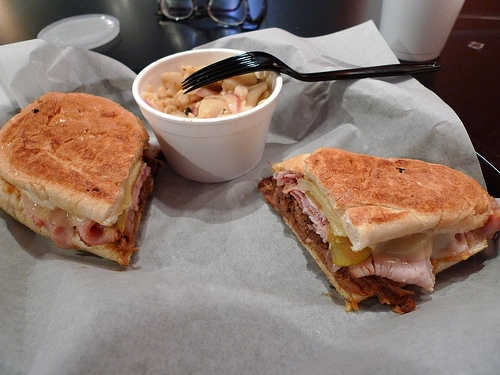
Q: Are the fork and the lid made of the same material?
A: Yes, both the fork and the lid are made of plastic.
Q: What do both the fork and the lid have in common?
A: The material, both the fork and the lid are plastic.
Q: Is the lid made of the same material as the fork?
A: Yes, both the lid and the fork are made of plastic.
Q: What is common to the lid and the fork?
A: The material, both the lid and the fork are plastic.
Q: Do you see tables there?
A: Yes, there is a table.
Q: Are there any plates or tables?
A: Yes, there is a table.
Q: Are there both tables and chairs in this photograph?
A: No, there is a table but no chairs.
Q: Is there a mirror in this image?
A: No, there are no mirrors.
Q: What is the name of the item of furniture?
A: The piece of furniture is a table.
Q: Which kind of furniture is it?
A: The piece of furniture is a table.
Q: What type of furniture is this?
A: That is a table.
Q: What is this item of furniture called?
A: That is a table.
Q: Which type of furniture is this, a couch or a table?
A: That is a table.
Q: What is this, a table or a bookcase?
A: This is a table.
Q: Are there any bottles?
A: No, there are no bottles.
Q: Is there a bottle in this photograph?
A: No, there are no bottles.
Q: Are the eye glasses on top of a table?
A: Yes, the eye glasses are on top of a table.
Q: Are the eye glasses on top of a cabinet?
A: No, the eye glasses are on top of a table.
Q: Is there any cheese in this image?
A: Yes, there is cheese.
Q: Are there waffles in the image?
A: No, there are no waffles.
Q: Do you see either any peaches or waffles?
A: No, there are no waffles or peaches.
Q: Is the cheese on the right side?
A: Yes, the cheese is on the right of the image.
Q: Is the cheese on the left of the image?
A: No, the cheese is on the right of the image.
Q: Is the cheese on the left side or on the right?
A: The cheese is on the right of the image.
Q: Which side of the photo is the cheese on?
A: The cheese is on the right of the image.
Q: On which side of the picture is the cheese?
A: The cheese is on the right of the image.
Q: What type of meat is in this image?
A: The meat is ham.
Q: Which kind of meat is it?
A: The meat is ham.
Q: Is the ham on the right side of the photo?
A: Yes, the ham is on the right of the image.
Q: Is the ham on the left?
A: No, the ham is on the right of the image.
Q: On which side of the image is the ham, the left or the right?
A: The ham is on the right of the image.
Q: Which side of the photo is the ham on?
A: The ham is on the right of the image.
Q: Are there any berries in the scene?
A: No, there are no berries.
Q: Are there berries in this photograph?
A: No, there are no berries.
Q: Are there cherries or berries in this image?
A: No, there are no berries or cherries.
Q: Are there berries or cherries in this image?
A: No, there are no berries or cherries.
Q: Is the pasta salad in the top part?
A: Yes, the pasta salad is in the top of the image.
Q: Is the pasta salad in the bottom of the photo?
A: No, the pasta salad is in the top of the image.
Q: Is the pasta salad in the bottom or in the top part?
A: The pasta salad is in the top of the image.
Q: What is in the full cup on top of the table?
A: The pasta salad is in the cup.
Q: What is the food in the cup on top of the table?
A: The food is pasta salad.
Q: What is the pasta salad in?
A: The pasta salad is in the cup.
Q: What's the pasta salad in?
A: The pasta salad is in the cup.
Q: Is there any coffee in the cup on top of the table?
A: No, there is pasta salad in the cup.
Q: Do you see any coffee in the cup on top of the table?
A: No, there is pasta salad in the cup.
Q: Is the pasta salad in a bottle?
A: No, the pasta salad is in the cup.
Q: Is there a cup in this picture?
A: Yes, there is a cup.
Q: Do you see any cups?
A: Yes, there is a cup.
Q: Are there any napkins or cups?
A: Yes, there is a cup.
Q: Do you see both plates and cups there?
A: No, there is a cup but no plates.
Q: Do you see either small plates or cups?
A: Yes, there is a small cup.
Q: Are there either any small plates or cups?
A: Yes, there is a small cup.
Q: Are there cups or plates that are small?
A: Yes, the cup is small.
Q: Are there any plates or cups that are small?
A: Yes, the cup is small.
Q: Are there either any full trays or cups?
A: Yes, there is a full cup.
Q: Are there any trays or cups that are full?
A: Yes, the cup is full.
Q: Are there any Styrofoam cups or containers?
A: Yes, there is a Styrofoam cup.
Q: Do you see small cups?
A: Yes, there is a small cup.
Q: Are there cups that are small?
A: Yes, there is a cup that is small.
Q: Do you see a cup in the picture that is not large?
A: Yes, there is a small cup.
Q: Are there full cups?
A: Yes, there is a full cup.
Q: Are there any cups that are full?
A: Yes, there is a cup that is full.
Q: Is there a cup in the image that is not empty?
A: Yes, there is an full cup.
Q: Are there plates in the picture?
A: No, there are no plates.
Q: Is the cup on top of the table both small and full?
A: Yes, the cup is small and full.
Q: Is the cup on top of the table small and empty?
A: No, the cup is small but full.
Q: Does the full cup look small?
A: Yes, the cup is small.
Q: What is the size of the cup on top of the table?
A: The cup is small.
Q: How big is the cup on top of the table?
A: The cup is small.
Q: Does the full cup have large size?
A: No, the cup is small.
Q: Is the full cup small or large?
A: The cup is small.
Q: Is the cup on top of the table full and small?
A: Yes, the cup is full and small.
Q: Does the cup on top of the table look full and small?
A: Yes, the cup is full and small.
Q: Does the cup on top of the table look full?
A: Yes, the cup is full.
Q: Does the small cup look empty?
A: No, the cup is full.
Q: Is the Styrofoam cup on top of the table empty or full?
A: The cup is full.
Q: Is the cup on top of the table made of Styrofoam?
A: Yes, the cup is made of styrofoam.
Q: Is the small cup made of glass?
A: No, the cup is made of styrofoam.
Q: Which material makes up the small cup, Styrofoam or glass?
A: The cup is made of styrofoam.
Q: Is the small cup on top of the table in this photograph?
A: Yes, the cup is on top of the table.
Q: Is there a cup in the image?
A: Yes, there is a cup.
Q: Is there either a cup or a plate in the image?
A: Yes, there is a cup.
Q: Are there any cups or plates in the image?
A: Yes, there is a cup.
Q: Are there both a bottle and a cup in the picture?
A: No, there is a cup but no bottles.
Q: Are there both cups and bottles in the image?
A: No, there is a cup but no bottles.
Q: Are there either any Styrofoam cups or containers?
A: Yes, there is a Styrofoam cup.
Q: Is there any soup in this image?
A: No, there is no soup.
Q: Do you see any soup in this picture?
A: No, there is no soup.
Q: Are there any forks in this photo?
A: Yes, there is a fork.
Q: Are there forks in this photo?
A: Yes, there is a fork.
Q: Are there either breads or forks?
A: Yes, there is a fork.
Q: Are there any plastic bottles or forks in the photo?
A: Yes, there is a plastic fork.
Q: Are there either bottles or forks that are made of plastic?
A: Yes, the fork is made of plastic.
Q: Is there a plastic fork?
A: Yes, there is a fork that is made of plastic.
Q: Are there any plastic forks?
A: Yes, there is a fork that is made of plastic.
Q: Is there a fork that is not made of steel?
A: Yes, there is a fork that is made of plastic.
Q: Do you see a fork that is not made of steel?
A: Yes, there is a fork that is made of plastic.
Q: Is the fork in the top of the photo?
A: Yes, the fork is in the top of the image.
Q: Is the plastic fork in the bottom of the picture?
A: No, the fork is in the top of the image.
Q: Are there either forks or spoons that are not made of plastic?
A: No, there is a fork but it is made of plastic.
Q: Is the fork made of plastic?
A: Yes, the fork is made of plastic.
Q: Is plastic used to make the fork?
A: Yes, the fork is made of plastic.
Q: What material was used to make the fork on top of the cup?
A: The fork is made of plastic.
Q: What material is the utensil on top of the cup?
A: The fork is made of plastic.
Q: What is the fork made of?
A: The fork is made of plastic.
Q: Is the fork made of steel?
A: No, the fork is made of plastic.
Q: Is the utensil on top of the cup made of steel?
A: No, the fork is made of plastic.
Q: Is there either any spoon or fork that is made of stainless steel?
A: No, there is a fork but it is made of plastic.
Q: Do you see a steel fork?
A: No, there is a fork but it is made of plastic.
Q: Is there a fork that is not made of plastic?
A: No, there is a fork but it is made of plastic.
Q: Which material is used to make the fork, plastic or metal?
A: The fork is made of plastic.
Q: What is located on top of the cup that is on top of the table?
A: The fork is on top of the cup.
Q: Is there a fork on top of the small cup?
A: Yes, there is a fork on top of the cup.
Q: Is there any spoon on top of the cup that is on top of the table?
A: No, there is a fork on top of the cup.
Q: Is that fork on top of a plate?
A: No, the fork is on top of a cup.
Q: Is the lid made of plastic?
A: Yes, the lid is made of plastic.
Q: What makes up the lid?
A: The lid is made of plastic.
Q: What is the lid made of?
A: The lid is made of plastic.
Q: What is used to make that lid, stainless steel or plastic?
A: The lid is made of plastic.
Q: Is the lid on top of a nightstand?
A: No, the lid is on top of the table.